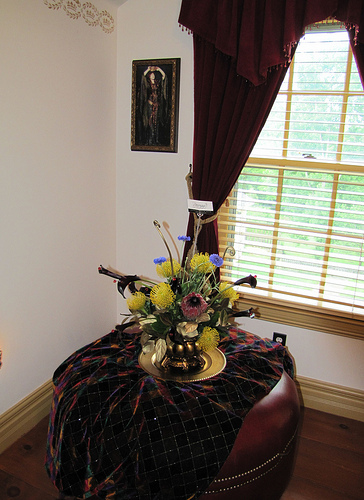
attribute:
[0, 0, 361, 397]
wall — white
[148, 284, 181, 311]
flower — yellow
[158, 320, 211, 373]
vase — gold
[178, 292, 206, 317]
flower — pink, red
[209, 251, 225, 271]
flower — blue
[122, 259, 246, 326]
flowers — yellow, red, blue, purple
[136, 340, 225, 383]
plate — gold, golden, yellow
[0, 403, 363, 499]
floors — brown, hard wood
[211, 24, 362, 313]
blinds — open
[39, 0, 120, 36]
design — gold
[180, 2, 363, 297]
curtains — burgundy, red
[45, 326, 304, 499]
cushion — red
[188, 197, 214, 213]
card — white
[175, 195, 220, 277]
stand — plastic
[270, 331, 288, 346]
outlet — black, white